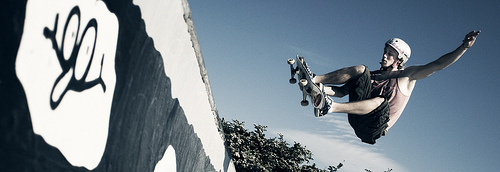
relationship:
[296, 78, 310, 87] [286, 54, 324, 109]
wheel on a skateboard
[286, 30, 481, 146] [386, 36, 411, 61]
boy wearing a helmet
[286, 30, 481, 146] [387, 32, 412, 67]
boy wearing helmet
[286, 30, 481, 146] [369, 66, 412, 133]
boy wearing tank top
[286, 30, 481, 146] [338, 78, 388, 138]
boy wearing short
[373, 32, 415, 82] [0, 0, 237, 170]
face on ramp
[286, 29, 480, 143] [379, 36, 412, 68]
boy wearing helmet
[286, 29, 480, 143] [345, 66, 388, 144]
boy wearing shorts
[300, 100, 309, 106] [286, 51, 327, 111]
wheel on skateboard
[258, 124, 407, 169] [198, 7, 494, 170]
cloud in sky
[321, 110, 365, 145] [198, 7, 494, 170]
cloud in sky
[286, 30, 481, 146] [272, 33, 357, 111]
boy wearing shoes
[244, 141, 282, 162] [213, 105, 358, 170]
leaves on tree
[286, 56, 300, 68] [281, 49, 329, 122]
wheel on skateboard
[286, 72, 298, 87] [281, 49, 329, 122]
wheel on skateboard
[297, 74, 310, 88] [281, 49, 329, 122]
wheel on skateboard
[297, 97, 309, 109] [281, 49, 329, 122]
wheel on skateboard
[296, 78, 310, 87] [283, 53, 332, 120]
wheel on skateboard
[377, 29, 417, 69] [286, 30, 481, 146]
helmet. on boy